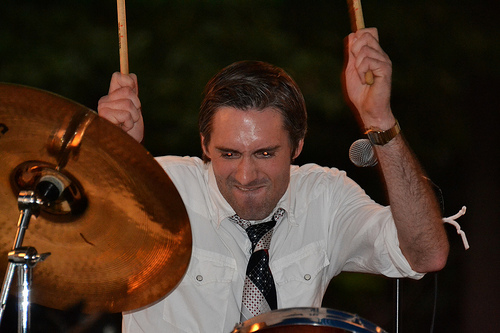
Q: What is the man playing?
A: Drums.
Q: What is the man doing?
A: Playing drums.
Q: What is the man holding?
A: Drumsticks.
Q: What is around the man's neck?
A: A tie.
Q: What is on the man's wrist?
A: A watch.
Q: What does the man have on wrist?
A: Watch.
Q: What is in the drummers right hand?
A: Drumstick.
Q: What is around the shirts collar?
A: Tie.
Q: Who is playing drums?
A: The man.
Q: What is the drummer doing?
A: Concentrating.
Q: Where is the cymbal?
A: On the drum set.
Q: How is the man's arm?
A: Hairy.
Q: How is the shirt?
A: White.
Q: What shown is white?
A: The shirt.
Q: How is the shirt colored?
A: White.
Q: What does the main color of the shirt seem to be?
A: White.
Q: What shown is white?
A: Shirt.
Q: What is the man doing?
A: Playing in a band.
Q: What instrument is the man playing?
A: The drums.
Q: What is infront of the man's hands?
A: A drumset.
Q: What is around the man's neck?
A: A tie.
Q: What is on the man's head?
A: His hair.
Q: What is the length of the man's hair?
A: Short.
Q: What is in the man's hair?
A: Gel.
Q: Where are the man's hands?
A: In the air.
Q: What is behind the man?
A: Microphone.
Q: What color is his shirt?
A: White.